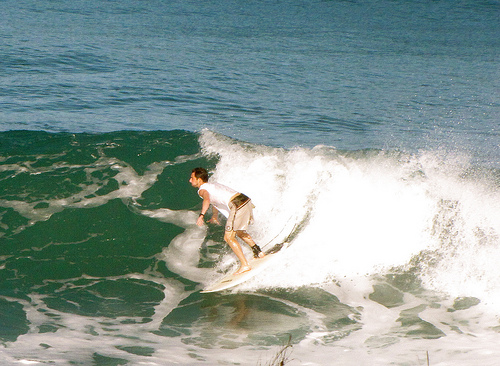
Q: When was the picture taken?
A: Daytime.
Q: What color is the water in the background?
A: Blue.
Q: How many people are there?
A: One.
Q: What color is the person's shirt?
A: White.